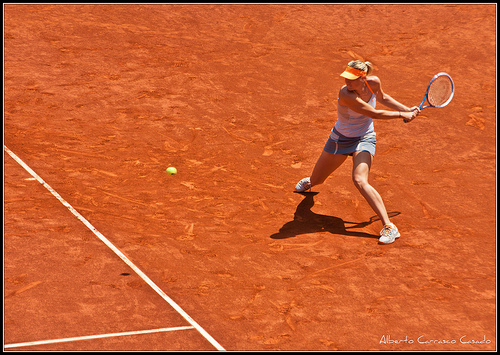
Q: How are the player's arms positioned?
A: Both are to the far right of the player's body.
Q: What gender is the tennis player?
A: Female.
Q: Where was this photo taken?
A: At a tennis court.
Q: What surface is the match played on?
A: Clay.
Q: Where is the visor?
A: On the player's head.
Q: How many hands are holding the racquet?
A: Two.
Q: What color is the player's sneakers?
A: White.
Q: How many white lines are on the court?
A: Two.